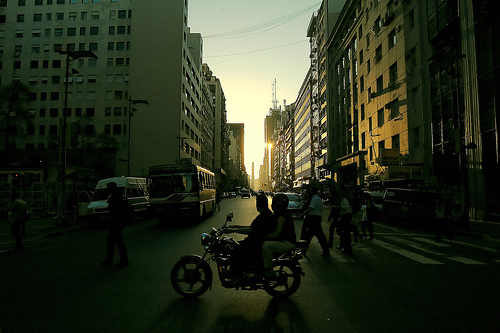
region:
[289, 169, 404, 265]
people crossing the street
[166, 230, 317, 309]
Motorcycle in the road.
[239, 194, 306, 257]
Two people on the bike.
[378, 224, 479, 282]
White lines on the road.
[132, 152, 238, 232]
Bus on the road.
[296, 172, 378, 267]
Group of people crossing the street.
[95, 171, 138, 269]
Single person crossing the street.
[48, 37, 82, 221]
Streetlights on the sidewalk.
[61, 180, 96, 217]
The door is open.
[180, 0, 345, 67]
Powerlines over the buildings.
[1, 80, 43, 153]
The tree is green.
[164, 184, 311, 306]
two people on a motorbike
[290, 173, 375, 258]
group of people crossing the street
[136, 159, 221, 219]
bus stopped on the street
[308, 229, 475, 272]
faded white crosswalk on the road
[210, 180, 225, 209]
person walking behind the bus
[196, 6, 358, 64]
powerlines running across the street and over the tops of buildings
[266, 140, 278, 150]
glint of the sun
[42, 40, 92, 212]
street lamp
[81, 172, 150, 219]
white van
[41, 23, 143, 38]
row of windows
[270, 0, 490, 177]
a street full of apartment buildings.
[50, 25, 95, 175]
a long pole with a flag.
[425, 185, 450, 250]
a woman standing in the street.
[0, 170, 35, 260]
a man crossing the street.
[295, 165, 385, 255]
a bunch of people are crossing the street.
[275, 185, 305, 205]
a white vehicle is parked in the street.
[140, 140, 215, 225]
a huge bus is driving down the street.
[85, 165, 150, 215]
a white van is parked near the bus.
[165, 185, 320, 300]
a man and woman is on the motorcycle.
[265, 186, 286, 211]
a woman is wearing a black helmet.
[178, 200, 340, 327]
couple riding on motorbike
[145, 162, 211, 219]
front of city bus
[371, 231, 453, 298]
white lines on street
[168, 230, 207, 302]
black tire on front of motorbike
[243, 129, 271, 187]
very bright light in distance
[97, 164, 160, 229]
white van near bus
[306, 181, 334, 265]
person wearing black pants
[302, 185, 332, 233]
person wearing white shirt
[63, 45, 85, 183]
black lamp post on street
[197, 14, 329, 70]
electrical wires between buildings